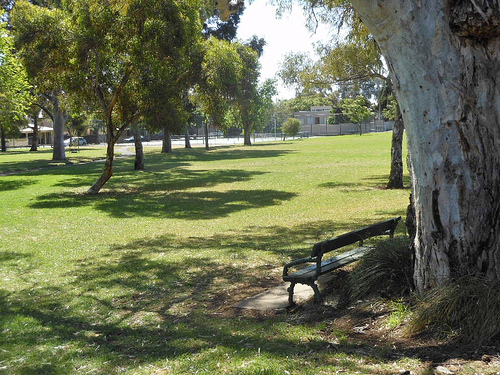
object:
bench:
[271, 205, 431, 311]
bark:
[360, 0, 500, 320]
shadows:
[0, 134, 299, 221]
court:
[151, 121, 314, 147]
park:
[0, 0, 500, 371]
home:
[7, 123, 54, 149]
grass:
[350, 237, 499, 350]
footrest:
[276, 276, 329, 309]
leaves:
[213, 57, 239, 83]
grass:
[0, 131, 413, 372]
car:
[56, 133, 91, 152]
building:
[284, 102, 382, 138]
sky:
[217, 0, 365, 103]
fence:
[293, 119, 397, 138]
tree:
[15, 1, 244, 207]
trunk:
[85, 97, 122, 201]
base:
[403, 236, 500, 289]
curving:
[98, 152, 116, 175]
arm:
[280, 257, 322, 284]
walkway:
[4, 140, 133, 186]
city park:
[0, 139, 500, 372]